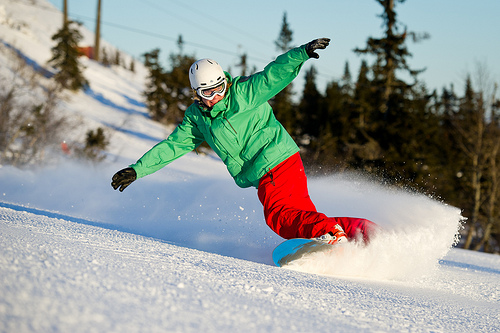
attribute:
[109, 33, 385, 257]
person — coasting, nice, boarding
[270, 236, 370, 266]
snowboard — kicking, blue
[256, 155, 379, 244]
pants — red, puffy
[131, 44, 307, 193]
jacket — green, puffy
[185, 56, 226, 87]
helmet — whtie, white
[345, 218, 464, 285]
snow — hard, laying, white, untouched, spraying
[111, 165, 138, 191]
glove — leather, black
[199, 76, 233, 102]
goggles — white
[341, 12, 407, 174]
tree — small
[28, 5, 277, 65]
wire — black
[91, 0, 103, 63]
pole — wooden